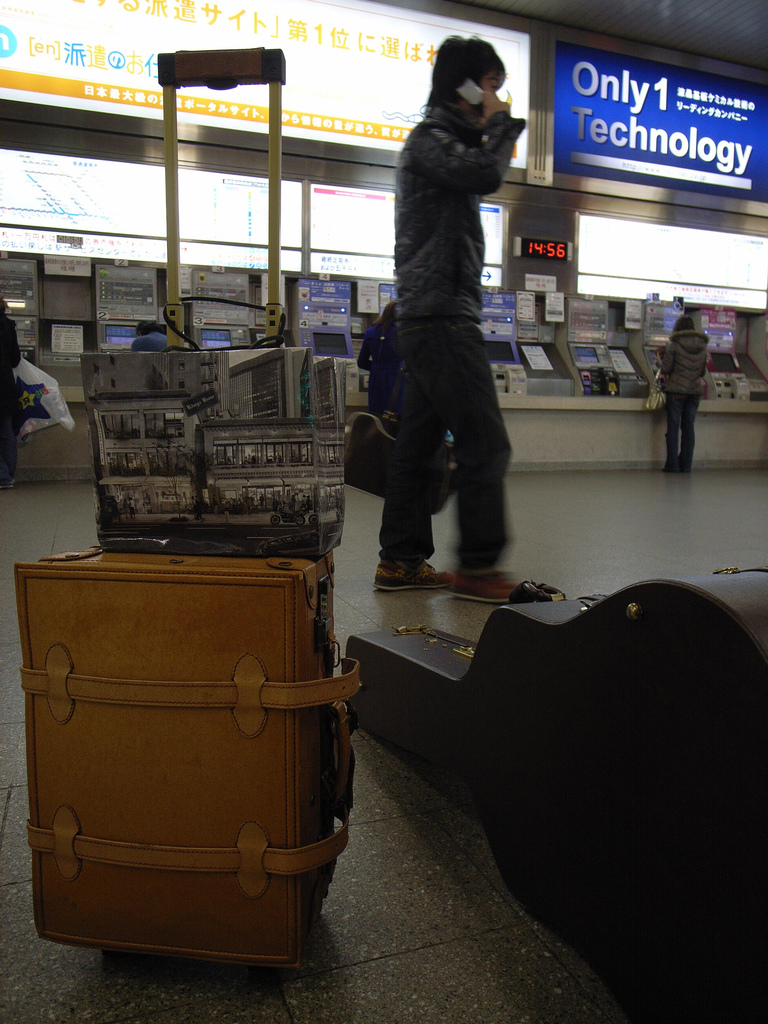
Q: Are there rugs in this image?
A: No, there are no rugs.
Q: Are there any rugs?
A: No, there are no rugs.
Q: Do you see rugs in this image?
A: No, there are no rugs.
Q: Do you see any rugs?
A: No, there are no rugs.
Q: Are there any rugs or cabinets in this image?
A: No, there are no rugs or cabinets.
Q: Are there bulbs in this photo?
A: No, there are no bulbs.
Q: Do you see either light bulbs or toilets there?
A: No, there are no light bulbs or toilets.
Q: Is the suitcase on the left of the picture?
A: Yes, the suitcase is on the left of the image.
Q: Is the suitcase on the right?
A: No, the suitcase is on the left of the image.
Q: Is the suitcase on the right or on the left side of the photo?
A: The suitcase is on the left of the image.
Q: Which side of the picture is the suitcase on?
A: The suitcase is on the left of the image.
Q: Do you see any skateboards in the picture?
A: No, there are no skateboards.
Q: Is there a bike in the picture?
A: No, there are no bikes.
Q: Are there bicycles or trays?
A: No, there are no bicycles or trays.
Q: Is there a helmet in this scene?
A: No, there are no helmets.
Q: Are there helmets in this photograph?
A: No, there are no helmets.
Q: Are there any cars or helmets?
A: No, there are no helmets or cars.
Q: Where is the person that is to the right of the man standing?
A: The person is standing at the counter.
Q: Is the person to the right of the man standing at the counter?
A: Yes, the person is standing at the counter.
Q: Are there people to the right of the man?
A: Yes, there is a person to the right of the man.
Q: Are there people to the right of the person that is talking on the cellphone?
A: Yes, there is a person to the right of the man.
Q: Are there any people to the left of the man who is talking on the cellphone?
A: No, the person is to the right of the man.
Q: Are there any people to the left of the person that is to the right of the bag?
A: No, the person is to the right of the man.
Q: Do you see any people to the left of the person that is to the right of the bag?
A: No, the person is to the right of the man.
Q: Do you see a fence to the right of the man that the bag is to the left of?
A: No, there is a person to the right of the man.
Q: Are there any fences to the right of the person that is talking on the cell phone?
A: No, there is a person to the right of the man.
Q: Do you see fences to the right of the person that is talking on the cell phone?
A: No, there is a person to the right of the man.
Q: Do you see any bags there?
A: Yes, there is a bag.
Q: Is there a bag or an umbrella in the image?
A: Yes, there is a bag.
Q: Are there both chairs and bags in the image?
A: No, there is a bag but no chairs.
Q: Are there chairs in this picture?
A: No, there are no chairs.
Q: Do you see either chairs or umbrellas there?
A: No, there are no chairs or umbrellas.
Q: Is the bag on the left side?
A: Yes, the bag is on the left of the image.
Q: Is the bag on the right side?
A: No, the bag is on the left of the image.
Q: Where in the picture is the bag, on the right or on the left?
A: The bag is on the left of the image.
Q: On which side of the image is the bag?
A: The bag is on the left of the image.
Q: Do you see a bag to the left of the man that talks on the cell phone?
A: Yes, there is a bag to the left of the man.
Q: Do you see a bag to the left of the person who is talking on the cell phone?
A: Yes, there is a bag to the left of the man.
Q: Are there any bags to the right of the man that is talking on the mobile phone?
A: No, the bag is to the left of the man.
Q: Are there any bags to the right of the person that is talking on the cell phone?
A: No, the bag is to the left of the man.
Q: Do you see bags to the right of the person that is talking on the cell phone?
A: No, the bag is to the left of the man.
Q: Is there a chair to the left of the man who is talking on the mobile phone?
A: No, there is a bag to the left of the man.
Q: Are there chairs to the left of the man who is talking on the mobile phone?
A: No, there is a bag to the left of the man.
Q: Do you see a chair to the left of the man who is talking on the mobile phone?
A: No, there is a bag to the left of the man.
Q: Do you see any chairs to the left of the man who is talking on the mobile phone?
A: No, there is a bag to the left of the man.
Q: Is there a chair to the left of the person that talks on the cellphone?
A: No, there is a bag to the left of the man.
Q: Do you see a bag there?
A: Yes, there is a bag.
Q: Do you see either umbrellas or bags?
A: Yes, there is a bag.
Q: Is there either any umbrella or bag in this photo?
A: Yes, there is a bag.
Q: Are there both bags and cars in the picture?
A: No, there is a bag but no cars.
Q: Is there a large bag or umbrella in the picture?
A: Yes, there is a large bag.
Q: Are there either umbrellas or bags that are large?
A: Yes, the bag is large.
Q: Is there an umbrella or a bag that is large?
A: Yes, the bag is large.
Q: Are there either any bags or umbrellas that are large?
A: Yes, the bag is large.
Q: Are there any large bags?
A: Yes, there is a large bag.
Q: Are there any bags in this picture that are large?
A: Yes, there is a bag that is large.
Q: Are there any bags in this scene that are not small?
A: Yes, there is a large bag.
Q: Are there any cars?
A: No, there are no cars.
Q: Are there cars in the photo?
A: No, there are no cars.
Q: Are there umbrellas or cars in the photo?
A: No, there are no cars or umbrellas.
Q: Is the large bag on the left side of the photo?
A: Yes, the bag is on the left of the image.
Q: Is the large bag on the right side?
A: No, the bag is on the left of the image.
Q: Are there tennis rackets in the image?
A: No, there are no tennis rackets.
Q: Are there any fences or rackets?
A: No, there are no rackets or fences.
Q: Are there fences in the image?
A: No, there are no fences.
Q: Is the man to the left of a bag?
A: No, the man is to the right of a bag.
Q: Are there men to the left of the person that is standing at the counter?
A: Yes, there is a man to the left of the person.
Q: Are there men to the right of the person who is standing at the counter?
A: No, the man is to the left of the person.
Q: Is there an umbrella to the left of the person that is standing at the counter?
A: No, there is a man to the left of the person.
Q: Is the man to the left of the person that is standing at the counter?
A: Yes, the man is to the left of the person.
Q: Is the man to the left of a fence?
A: No, the man is to the left of the person.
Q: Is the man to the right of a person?
A: No, the man is to the left of a person.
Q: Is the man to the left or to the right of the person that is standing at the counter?
A: The man is to the left of the person.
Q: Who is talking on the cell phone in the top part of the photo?
A: The man is talking on the mobile phone.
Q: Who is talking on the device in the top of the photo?
A: The man is talking on the mobile phone.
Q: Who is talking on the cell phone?
A: The man is talking on the mobile phone.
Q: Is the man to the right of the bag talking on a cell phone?
A: Yes, the man is talking on a cell phone.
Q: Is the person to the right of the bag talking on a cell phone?
A: Yes, the man is talking on a cell phone.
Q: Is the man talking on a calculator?
A: No, the man is talking on a cell phone.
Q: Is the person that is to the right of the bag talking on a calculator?
A: No, the man is talking on a cell phone.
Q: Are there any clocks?
A: Yes, there is a clock.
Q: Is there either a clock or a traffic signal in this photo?
A: Yes, there is a clock.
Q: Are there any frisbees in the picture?
A: No, there are no frisbees.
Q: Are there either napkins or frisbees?
A: No, there are no frisbees or napkins.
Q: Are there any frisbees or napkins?
A: No, there are no frisbees or napkins.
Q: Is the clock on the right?
A: Yes, the clock is on the right of the image.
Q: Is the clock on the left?
A: No, the clock is on the right of the image.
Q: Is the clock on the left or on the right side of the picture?
A: The clock is on the right of the image.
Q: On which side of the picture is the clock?
A: The clock is on the right of the image.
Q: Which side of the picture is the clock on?
A: The clock is on the right of the image.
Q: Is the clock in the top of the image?
A: Yes, the clock is in the top of the image.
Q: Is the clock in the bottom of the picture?
A: No, the clock is in the top of the image.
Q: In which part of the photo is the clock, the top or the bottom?
A: The clock is in the top of the image.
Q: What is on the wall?
A: The clock is on the wall.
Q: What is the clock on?
A: The clock is on the wall.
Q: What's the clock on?
A: The clock is on the wall.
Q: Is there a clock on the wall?
A: Yes, there is a clock on the wall.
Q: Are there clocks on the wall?
A: Yes, there is a clock on the wall.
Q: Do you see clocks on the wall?
A: Yes, there is a clock on the wall.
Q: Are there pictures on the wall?
A: No, there is a clock on the wall.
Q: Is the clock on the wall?
A: Yes, the clock is on the wall.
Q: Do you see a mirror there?
A: No, there are no mirrors.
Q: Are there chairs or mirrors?
A: No, there are no mirrors or chairs.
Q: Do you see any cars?
A: No, there are no cars.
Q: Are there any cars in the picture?
A: No, there are no cars.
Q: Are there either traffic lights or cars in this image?
A: No, there are no cars or traffic lights.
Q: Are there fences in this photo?
A: No, there are no fences.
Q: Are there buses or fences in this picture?
A: No, there are no fences or buses.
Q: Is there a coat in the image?
A: Yes, there is a coat.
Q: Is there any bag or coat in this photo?
A: Yes, there is a coat.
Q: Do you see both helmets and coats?
A: No, there is a coat but no helmets.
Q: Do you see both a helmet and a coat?
A: No, there is a coat but no helmets.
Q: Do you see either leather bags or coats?
A: Yes, there is a leather coat.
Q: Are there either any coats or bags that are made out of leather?
A: Yes, the coat is made of leather.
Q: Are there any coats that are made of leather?
A: Yes, there is a coat that is made of leather.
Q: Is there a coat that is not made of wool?
A: Yes, there is a coat that is made of leather.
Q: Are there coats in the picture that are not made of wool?
A: Yes, there is a coat that is made of leather.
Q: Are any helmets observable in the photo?
A: No, there are no helmets.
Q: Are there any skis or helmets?
A: No, there are no helmets or skis.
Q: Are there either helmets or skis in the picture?
A: No, there are no helmets or skis.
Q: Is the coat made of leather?
A: Yes, the coat is made of leather.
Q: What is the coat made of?
A: The coat is made of leather.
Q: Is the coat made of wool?
A: No, the coat is made of leather.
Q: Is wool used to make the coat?
A: No, the coat is made of leather.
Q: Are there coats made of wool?
A: No, there is a coat but it is made of leather.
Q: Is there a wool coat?
A: No, there is a coat but it is made of leather.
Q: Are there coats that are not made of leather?
A: No, there is a coat but it is made of leather.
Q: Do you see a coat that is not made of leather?
A: No, there is a coat but it is made of leather.